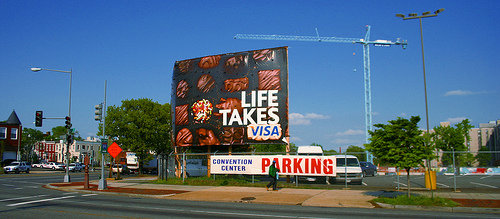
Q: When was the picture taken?
A: Daytime.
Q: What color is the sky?
A: Blue.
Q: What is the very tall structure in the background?
A: A crane.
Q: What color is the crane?
A: Light blue.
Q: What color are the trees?
A: Green.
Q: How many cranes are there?
A: One.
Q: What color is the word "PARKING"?
A: Red.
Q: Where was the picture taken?
A: Street corner.